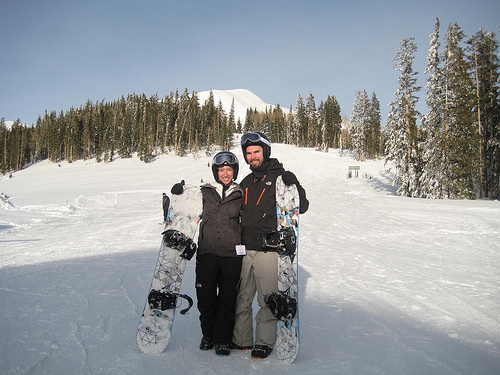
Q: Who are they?
A: People.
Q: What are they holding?
A: Snowboards.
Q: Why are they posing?
A: Photo.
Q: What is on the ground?
A: Snow.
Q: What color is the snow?
A: White.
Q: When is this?
A: Daytime.